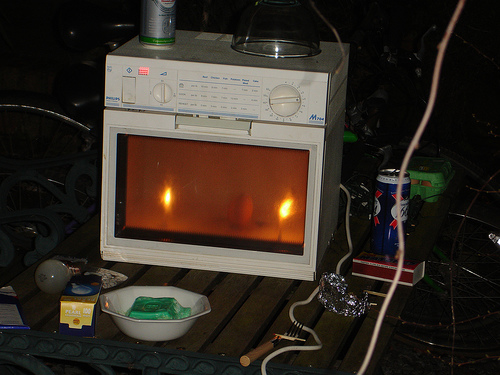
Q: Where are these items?
A: On a wooden table.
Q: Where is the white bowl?
A: In front of the oven.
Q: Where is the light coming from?
A: Inside the oven.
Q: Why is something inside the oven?
A: To be cooked.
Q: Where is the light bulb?
A: By the bowl.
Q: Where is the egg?
A: In the microwave.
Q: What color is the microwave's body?
A: White.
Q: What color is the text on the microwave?
A: Blue.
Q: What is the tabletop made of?
A: Wood.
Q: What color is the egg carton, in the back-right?
A: Green.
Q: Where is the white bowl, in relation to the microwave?
A: In front.